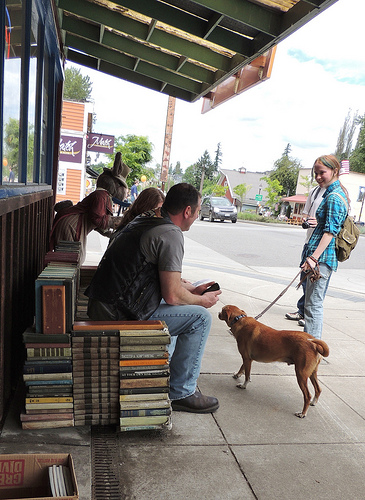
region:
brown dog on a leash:
[194, 254, 341, 417]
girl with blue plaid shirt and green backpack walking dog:
[291, 141, 339, 364]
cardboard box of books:
[2, 447, 91, 499]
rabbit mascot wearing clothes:
[53, 148, 133, 285]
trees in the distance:
[261, 144, 299, 231]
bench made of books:
[23, 239, 192, 452]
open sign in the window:
[2, 4, 15, 74]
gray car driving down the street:
[195, 196, 252, 230]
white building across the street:
[286, 151, 356, 221]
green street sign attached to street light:
[251, 181, 266, 217]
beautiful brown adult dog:
[219, 294, 332, 427]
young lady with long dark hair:
[275, 144, 350, 364]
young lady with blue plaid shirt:
[269, 145, 359, 328]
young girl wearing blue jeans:
[265, 147, 348, 379]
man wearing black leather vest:
[86, 178, 217, 331]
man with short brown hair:
[147, 174, 224, 232]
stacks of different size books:
[66, 318, 174, 443]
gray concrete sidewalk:
[186, 294, 337, 439]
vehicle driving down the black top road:
[155, 178, 267, 253]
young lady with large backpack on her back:
[269, 165, 356, 362]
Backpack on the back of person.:
[336, 204, 359, 267]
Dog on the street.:
[216, 303, 333, 417]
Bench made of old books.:
[24, 242, 178, 438]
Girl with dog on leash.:
[219, 149, 345, 420]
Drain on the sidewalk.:
[82, 433, 126, 497]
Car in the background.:
[195, 192, 246, 224]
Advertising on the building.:
[56, 96, 123, 202]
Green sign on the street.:
[248, 189, 268, 205]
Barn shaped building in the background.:
[209, 167, 291, 221]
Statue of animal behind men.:
[52, 146, 133, 253]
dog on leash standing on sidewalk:
[222, 293, 342, 415]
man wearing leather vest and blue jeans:
[105, 185, 236, 429]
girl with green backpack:
[287, 155, 355, 393]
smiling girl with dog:
[218, 147, 356, 416]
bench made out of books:
[31, 184, 206, 449]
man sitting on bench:
[29, 156, 232, 437]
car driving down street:
[201, 187, 256, 244]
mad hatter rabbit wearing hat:
[60, 142, 136, 257]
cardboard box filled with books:
[19, 449, 112, 498]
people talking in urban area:
[18, 73, 363, 464]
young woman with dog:
[216, 142, 356, 407]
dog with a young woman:
[214, 121, 351, 452]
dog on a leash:
[214, 251, 339, 429]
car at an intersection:
[199, 189, 234, 227]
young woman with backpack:
[281, 149, 362, 353]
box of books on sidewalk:
[1, 438, 79, 497]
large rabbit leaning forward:
[62, 137, 126, 281]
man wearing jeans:
[95, 176, 236, 438]